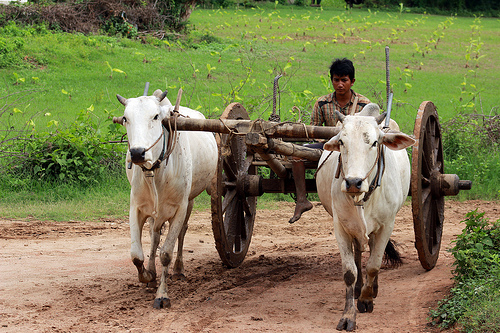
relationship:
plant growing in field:
[205, 63, 217, 75] [4, 0, 499, 57]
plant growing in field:
[205, 63, 217, 75] [8, 8, 499, 205]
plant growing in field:
[205, 63, 217, 75] [4, 3, 499, 115]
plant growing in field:
[205, 63, 217, 75] [271, 7, 487, 56]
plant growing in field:
[20, 120, 125, 191] [5, 3, 125, 218]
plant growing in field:
[205, 63, 217, 75] [5, 3, 125, 218]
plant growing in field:
[446, 189, 493, 314] [29, 7, 479, 188]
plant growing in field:
[205, 63, 217, 75] [9, 14, 496, 104]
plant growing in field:
[205, 63, 217, 75] [29, 7, 479, 188]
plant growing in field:
[463, 52, 489, 73] [0, 10, 498, 224]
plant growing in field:
[205, 63, 217, 75] [13, 13, 471, 196]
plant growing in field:
[205, 63, 217, 75] [237, 21, 369, 59]